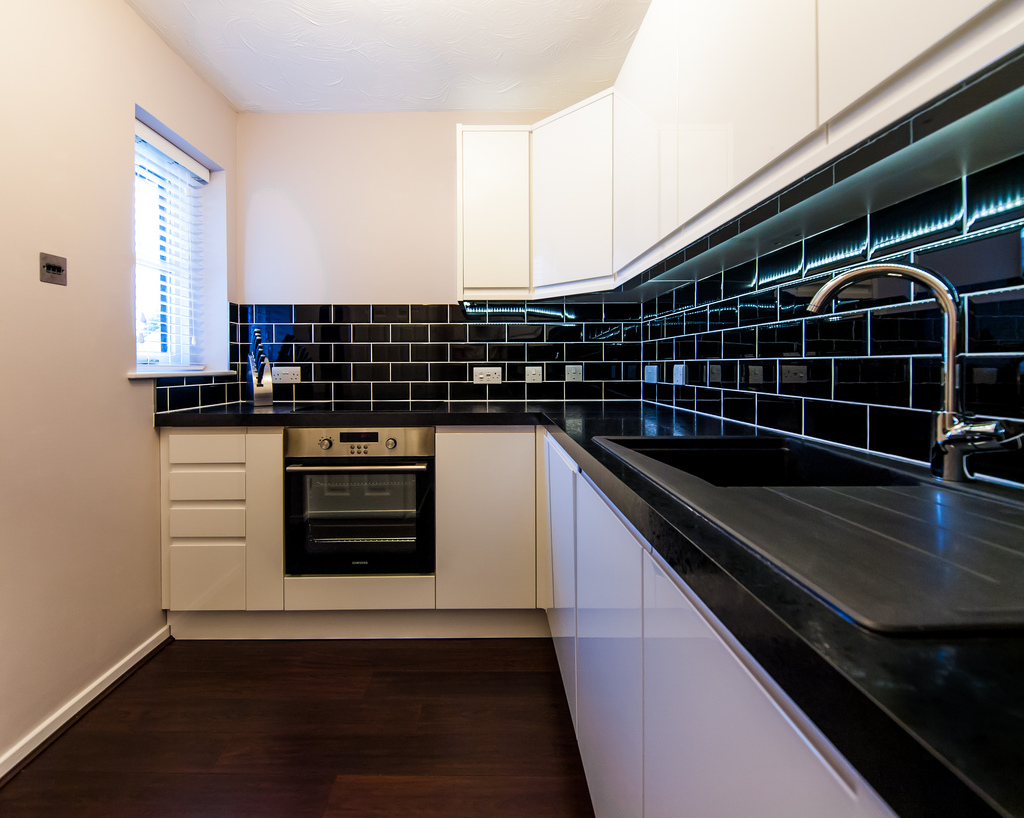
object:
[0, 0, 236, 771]
wall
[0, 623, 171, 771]
floor board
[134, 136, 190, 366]
window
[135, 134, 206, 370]
blinds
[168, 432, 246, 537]
drawer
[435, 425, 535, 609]
cabinet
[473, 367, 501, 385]
outlet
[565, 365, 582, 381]
tile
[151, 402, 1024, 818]
counter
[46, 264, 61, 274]
switches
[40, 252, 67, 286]
switch plate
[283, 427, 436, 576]
oven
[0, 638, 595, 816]
flooring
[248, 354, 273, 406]
holder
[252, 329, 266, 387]
knives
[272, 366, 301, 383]
socket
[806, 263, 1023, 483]
faucet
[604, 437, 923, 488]
sink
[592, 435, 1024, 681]
surround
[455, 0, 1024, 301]
cabinets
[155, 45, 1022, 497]
backsplash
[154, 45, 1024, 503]
grout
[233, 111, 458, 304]
wall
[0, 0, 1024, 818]
building